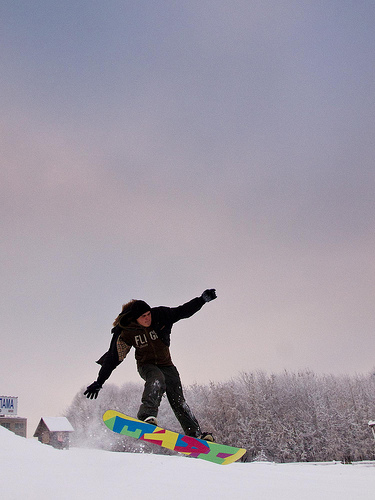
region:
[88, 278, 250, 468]
man snowboarding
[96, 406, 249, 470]
Multi colored snowboard with letters on it.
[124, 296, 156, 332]
Man with a black beanie on his head.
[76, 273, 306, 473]
Man performing a trick on his snowboard.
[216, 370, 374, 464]
wooded area with trees covered in snow.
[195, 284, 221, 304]
black snow glove on man's hand.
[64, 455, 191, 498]
ground covered in deep snow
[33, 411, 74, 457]
Small building in the back ground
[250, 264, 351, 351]
Cloudy and overcast sky.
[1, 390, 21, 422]
White sign with large blue letters.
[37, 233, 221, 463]
the man is wearing black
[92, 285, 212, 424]
the man is wearing black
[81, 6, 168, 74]
clear blue cloudless sky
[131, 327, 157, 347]
white writing on front of shirt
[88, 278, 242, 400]
man in black jacket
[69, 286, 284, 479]
snow boarder jumping in air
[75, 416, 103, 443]
snow particles in air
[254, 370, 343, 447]
brown trees covered in snow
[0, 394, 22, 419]
sign on top of building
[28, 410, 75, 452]
small building covered in snow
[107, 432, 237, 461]
design on bottom of snowboard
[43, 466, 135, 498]
ground covered in snow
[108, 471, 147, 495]
the snow is white and clear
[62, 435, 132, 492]
the snow is white and clear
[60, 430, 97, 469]
the snow is white and clear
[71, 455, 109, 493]
the snow is white and clear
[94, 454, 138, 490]
the snow is white and clear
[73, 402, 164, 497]
the snow is white and clear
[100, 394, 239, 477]
multicolored snowboard with letters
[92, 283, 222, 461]
person in black clothes snowboarding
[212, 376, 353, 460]
pine trees covered with snow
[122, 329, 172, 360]
black hoodie with white letters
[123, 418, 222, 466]
colorful letters on snowboard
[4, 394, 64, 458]
buildings in the distance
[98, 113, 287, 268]
partly cloudy blue sky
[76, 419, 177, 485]
snowboarder kicking up snow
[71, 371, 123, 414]
glove on snowboarder's hand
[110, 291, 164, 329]
snowboarder wearing black hat